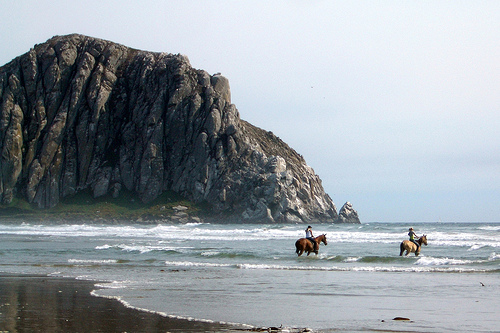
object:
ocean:
[0, 223, 499, 333]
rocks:
[339, 201, 361, 224]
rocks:
[171, 204, 202, 223]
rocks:
[0, 33, 361, 224]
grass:
[0, 189, 202, 225]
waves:
[0, 225, 499, 331]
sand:
[0, 273, 258, 332]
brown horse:
[400, 234, 428, 257]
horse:
[295, 233, 328, 257]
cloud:
[90, 0, 468, 141]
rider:
[408, 228, 419, 252]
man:
[305, 226, 317, 251]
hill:
[0, 33, 361, 225]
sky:
[0, 0, 499, 224]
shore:
[0, 271, 325, 333]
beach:
[0, 221, 499, 332]